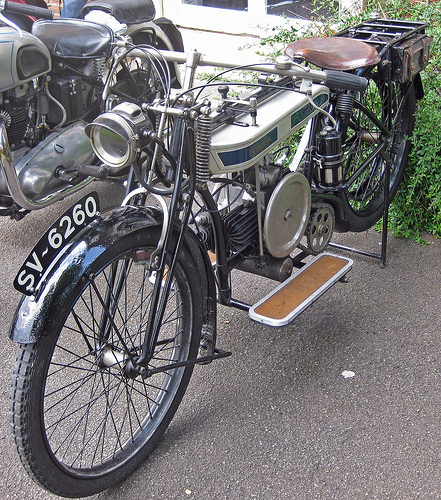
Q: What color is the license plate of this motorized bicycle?
A: Black.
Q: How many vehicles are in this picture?
A: 2.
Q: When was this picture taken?
A: Daytime.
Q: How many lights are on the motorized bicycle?
A: 1.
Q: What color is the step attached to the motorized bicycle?
A: Brown.